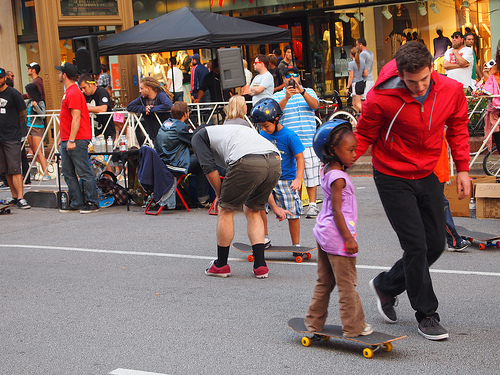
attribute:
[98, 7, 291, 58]
canopy — black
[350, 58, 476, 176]
jacket — red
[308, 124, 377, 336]
girl — young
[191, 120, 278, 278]
man — bent over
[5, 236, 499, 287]
line — white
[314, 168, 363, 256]
shirt — purple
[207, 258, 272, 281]
shoes — red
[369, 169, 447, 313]
pants — black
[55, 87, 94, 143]
shirt — red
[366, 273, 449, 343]
shoes — black